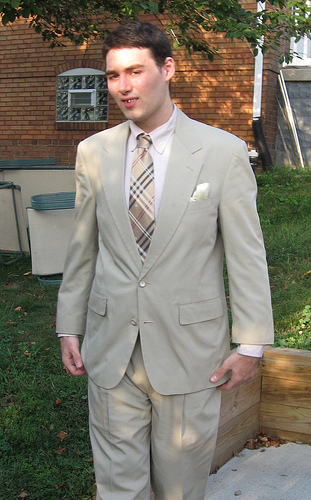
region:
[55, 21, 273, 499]
Man in a tan suit.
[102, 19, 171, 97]
Man has brown hair.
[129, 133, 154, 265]
Man is wearing a striped tie.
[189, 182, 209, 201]
Man has a tissue in his pocket.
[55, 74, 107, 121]
Window on the house.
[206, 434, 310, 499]
Cement slab on the ground.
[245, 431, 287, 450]
Pile of dead leaves on the cement slab.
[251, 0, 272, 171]
White and black gutter on the building.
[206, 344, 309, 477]
Wooden retainer wall next to the cement.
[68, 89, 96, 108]
A/C unit in the window.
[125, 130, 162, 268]
plaid beige neck tie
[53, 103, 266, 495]
tan suit jacket and pants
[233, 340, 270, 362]
tan cuff of shirt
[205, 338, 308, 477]
elevated wooden grass barrier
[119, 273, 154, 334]
buttons on front of suit jacket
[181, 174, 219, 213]
off white pocket square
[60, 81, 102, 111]
exterior window air conditioner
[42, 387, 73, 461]
brown leaves in grass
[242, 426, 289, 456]
brown leaves in corner of paved patch of ground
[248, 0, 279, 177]
white and black metal pipe on side of brick building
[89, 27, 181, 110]
a man with short hair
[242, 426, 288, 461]
brown leaves on the ground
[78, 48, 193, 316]
a young man wearing a business suit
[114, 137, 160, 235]
a young man wearing a tie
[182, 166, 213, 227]
a hankerchief in a pocket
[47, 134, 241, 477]
a young man with his hands to his sides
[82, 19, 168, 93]
a young man with brown hair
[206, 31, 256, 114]
a red brick building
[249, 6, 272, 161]
a white and black gutter spout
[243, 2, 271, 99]
a white metal gutter spout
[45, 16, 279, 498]
a boy is in a tan suit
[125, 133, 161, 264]
the boy has a shirt and tie on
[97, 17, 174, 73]
the boy has short brown hair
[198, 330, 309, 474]
a retaining wall is next to the man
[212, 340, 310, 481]
the retaining wall is wood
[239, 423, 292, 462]
leaves are in the corner of the retaining wall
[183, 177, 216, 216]
a white handkerchief is in the suit pocket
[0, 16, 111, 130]
an arched window is on the building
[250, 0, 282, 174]
a gutter system is on the corner of the building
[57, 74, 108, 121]
glass block is in the window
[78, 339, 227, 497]
Man is wearing pants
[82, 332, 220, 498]
Man is wearing light colored pants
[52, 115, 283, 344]
Man is wearing a blazer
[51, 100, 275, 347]
Man is wearing a light colored blazer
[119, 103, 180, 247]
Man is wearing a shirt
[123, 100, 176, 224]
Man is wearing a white shirt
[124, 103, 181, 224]
Man is wearing a dress shirt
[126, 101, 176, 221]
Man is wearing a white dress shirt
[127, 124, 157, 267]
Man is wearing a tie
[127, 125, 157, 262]
Man wearing a tie